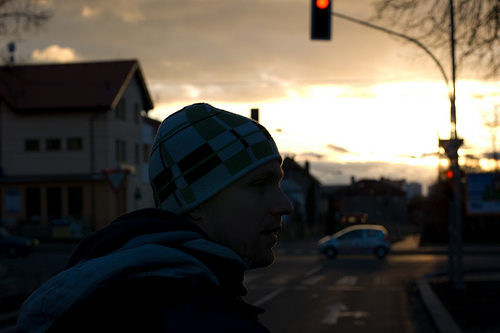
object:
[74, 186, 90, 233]
window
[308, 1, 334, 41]
light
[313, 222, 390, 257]
car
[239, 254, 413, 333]
crosswalk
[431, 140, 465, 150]
sign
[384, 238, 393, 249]
tail light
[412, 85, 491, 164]
sun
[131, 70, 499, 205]
background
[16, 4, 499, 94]
cloud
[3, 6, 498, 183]
sky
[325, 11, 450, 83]
pole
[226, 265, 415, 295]
lines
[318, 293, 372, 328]
arrow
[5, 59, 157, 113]
roof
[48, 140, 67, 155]
window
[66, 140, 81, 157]
window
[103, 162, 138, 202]
sign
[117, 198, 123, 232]
pole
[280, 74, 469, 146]
sunlight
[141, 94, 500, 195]
horizon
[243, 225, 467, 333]
intersection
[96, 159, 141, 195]
yield sign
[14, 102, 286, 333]
man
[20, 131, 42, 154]
window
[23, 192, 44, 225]
window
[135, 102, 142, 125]
window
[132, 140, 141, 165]
window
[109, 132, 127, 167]
window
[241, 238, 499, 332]
road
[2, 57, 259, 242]
apartments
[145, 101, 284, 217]
beanie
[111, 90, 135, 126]
window